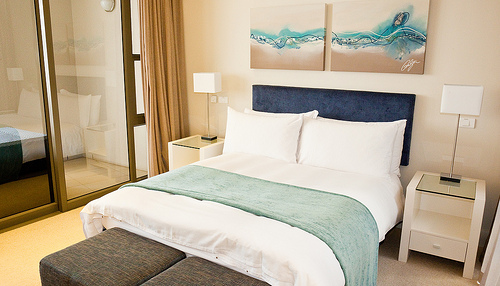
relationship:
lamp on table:
[424, 79, 492, 202] [163, 127, 236, 214]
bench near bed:
[38, 226, 188, 286] [82, 81, 415, 268]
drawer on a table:
[405, 229, 468, 264] [394, 165, 488, 278]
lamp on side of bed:
[192, 72, 223, 141] [35, 73, 421, 283]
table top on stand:
[413, 170, 488, 203] [388, 168, 490, 278]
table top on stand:
[168, 127, 225, 152] [166, 132, 241, 209]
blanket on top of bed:
[81, 155, 405, 286] [82, 81, 415, 268]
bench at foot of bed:
[38, 226, 188, 286] [64, 61, 431, 276]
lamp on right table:
[438, 84, 486, 185] [394, 165, 488, 278]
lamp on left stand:
[188, 65, 225, 112] [166, 134, 224, 172]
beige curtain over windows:
[136, 1, 188, 178] [0, 0, 147, 228]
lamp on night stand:
[192, 72, 223, 141] [166, 134, 223, 173]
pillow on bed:
[294, 114, 408, 179] [82, 81, 415, 268]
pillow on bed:
[223, 109, 300, 163] [82, 81, 415, 268]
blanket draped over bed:
[119, 160, 382, 284] [79, 82, 434, 279]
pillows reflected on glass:
[21, 86, 101, 132] [1, 0, 129, 215]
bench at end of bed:
[21, 212, 271, 282] [79, 82, 434, 279]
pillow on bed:
[294, 114, 409, 179] [79, 82, 434, 279]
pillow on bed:
[223, 109, 300, 163] [79, 82, 434, 279]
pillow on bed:
[220, 106, 304, 163] [79, 82, 434, 279]